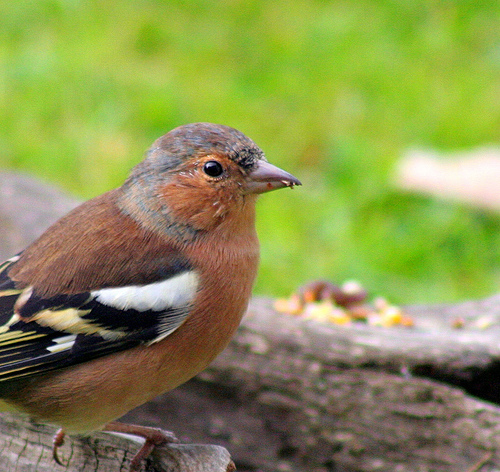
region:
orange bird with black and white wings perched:
[10, 118, 327, 453]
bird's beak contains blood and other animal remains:
[243, 163, 292, 195]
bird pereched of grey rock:
[5, 417, 248, 465]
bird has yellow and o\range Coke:
[63, 221, 243, 431]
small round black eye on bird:
[203, 155, 230, 186]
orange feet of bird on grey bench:
[48, 418, 188, 469]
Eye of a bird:
[203, 155, 232, 190]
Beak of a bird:
[248, 146, 305, 207]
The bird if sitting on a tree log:
[5, 81, 314, 461]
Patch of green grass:
[76, 15, 376, 98]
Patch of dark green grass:
[40, 20, 225, 102]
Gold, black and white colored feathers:
[37, 258, 179, 364]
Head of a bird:
[146, 100, 310, 255]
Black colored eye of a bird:
[197, 152, 227, 183]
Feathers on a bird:
[17, 199, 177, 380]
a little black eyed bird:
[0, 118, 300, 438]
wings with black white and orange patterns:
[0, 115, 312, 447]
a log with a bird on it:
[3, 174, 495, 468]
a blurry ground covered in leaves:
[9, 1, 499, 312]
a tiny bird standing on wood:
[2, 115, 304, 440]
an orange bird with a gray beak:
[0, 115, 312, 446]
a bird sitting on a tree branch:
[0, 118, 300, 435]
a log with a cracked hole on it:
[257, 283, 494, 467]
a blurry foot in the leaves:
[377, 117, 498, 217]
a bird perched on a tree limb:
[0, 117, 310, 468]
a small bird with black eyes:
[2, 118, 307, 452]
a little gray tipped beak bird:
[0, 121, 304, 452]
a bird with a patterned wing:
[0, 117, 315, 455]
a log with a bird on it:
[5, 167, 495, 469]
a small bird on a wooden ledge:
[0, 111, 301, 469]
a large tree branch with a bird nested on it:
[2, 87, 496, 469]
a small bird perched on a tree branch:
[0, 87, 495, 469]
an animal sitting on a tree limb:
[2, 88, 310, 469]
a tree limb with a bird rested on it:
[5, 124, 492, 469]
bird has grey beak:
[237, 158, 302, 223]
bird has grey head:
[157, 113, 265, 185]